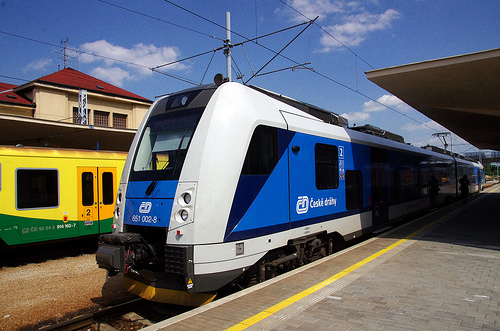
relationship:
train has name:
[92, 71, 482, 297] [295, 194, 338, 216]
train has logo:
[92, 71, 482, 297] [294, 195, 310, 214]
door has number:
[78, 167, 99, 235] [85, 208, 94, 216]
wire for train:
[159, 0, 438, 133] [92, 71, 482, 297]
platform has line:
[132, 183, 499, 330] [222, 185, 499, 330]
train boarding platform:
[92, 71, 482, 297] [132, 183, 499, 330]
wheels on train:
[0, 238, 22, 268] [92, 71, 482, 297]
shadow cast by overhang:
[385, 196, 483, 254] [363, 51, 500, 151]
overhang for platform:
[361, 52, 474, 142] [132, 183, 499, 330]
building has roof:
[0, 67, 153, 127] [14, 66, 152, 104]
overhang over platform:
[363, 51, 500, 151] [203, 190, 484, 316]